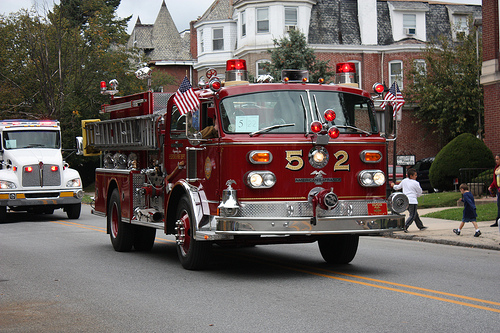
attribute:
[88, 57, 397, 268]
truck — fire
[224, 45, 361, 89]
lights — red, on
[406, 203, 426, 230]
black pants — grey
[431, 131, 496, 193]
bush — beautiful, dark green, tree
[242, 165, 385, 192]
lights — red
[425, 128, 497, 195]
bush — small, dark green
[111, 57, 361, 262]
truck — fire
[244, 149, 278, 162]
light — orange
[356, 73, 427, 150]
flag — American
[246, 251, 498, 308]
lines — yellow, parellel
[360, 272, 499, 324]
lines — yellow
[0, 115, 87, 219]
truck — white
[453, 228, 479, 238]
sneakers — grey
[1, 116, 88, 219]
vehicle — white